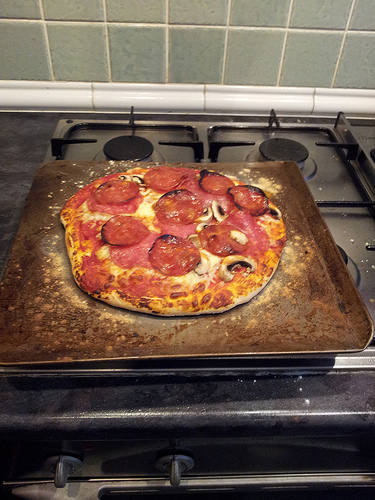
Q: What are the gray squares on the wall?
A: Ceramic tiles.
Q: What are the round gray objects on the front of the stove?
A: Control knobs.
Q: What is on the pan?
A: Pizza.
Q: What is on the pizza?
A: Toppings.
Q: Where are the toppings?
A: On the pizza.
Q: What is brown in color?
A: The crust.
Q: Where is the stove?
A: Under the pan.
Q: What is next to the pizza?
A: A wall.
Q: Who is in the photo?
A: No people.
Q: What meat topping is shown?
A: Pepperoni.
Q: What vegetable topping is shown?
A: Mushroom.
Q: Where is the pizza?
A: On cooking sheet.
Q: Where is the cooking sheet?
A: On stovetop.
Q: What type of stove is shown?
A: Gas.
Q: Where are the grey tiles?
A: On wall.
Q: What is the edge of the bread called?
A: Crust.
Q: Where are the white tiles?
A: At base of wall.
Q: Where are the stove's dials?
A: On its front.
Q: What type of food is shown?
A: A pizza.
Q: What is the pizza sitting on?
A: A tray.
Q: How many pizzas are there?
A: One.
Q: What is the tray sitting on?
A: A stove top.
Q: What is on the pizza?
A: Pepperoni, cheese, and mushrooms.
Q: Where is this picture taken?
A: In a kitchen.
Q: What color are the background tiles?
A: Gray.